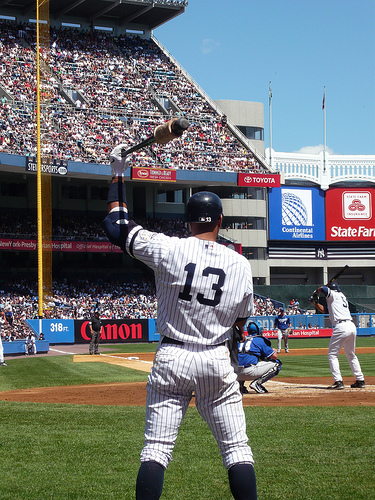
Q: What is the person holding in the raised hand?
A: Baseball bat.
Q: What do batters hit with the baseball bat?
A: Baseballs.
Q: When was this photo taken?
A: Daytime.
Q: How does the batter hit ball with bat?
A: By swinging bat.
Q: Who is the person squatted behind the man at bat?
A: Catcher.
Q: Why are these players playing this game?
A: It is their profession.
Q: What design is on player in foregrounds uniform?
A: Stripes.